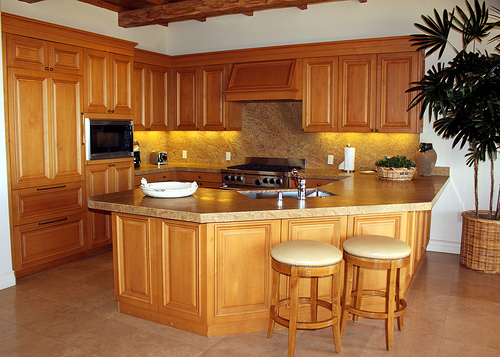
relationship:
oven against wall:
[221, 163, 303, 189] [129, 99, 429, 181]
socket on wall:
[222, 146, 234, 166] [169, 132, 240, 162]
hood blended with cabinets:
[233, 65, 290, 100] [167, 39, 419, 127]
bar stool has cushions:
[269, 236, 351, 349] [269, 239, 343, 268]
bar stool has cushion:
[338, 234, 412, 349] [343, 234, 411, 260]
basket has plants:
[376, 154, 417, 180] [418, 6, 498, 160]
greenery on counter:
[372, 155, 417, 168] [86, 169, 447, 224]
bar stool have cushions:
[265, 238, 343, 354] [269, 238, 346, 268]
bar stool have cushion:
[338, 234, 412, 349] [343, 233, 411, 257]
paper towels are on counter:
[340, 140, 365, 180] [77, 151, 454, 223]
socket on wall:
[321, 147, 339, 169] [300, 133, 419, 174]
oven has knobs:
[226, 131, 296, 202] [220, 166, 248, 182]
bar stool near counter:
[338, 234, 412, 349] [87, 162, 454, 336]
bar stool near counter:
[265, 238, 343, 354] [87, 162, 454, 336]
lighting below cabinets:
[122, 123, 263, 174] [144, 52, 240, 142]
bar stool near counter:
[338, 234, 412, 349] [82, 170, 452, 324]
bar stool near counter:
[265, 238, 343, 354] [82, 170, 452, 324]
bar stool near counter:
[265, 238, 343, 354] [86, 169, 447, 224]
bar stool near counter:
[338, 234, 412, 349] [86, 169, 447, 224]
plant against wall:
[403, 0, 498, 276] [3, 0, 499, 253]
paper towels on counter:
[339, 147, 355, 171] [86, 156, 453, 227]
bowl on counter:
[138, 177, 198, 198] [85, 190, 457, 247]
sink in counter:
[242, 186, 337, 199] [203, 189, 430, 214]